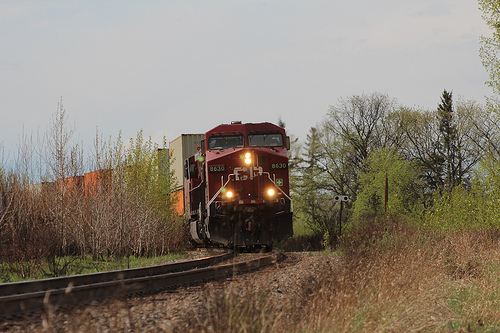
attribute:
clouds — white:
[2, 3, 487, 162]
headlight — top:
[241, 148, 254, 158]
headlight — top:
[240, 157, 254, 167]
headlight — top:
[262, 184, 279, 199]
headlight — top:
[222, 186, 236, 201]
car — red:
[182, 115, 294, 255]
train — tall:
[25, 120, 295, 250]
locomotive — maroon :
[189, 117, 296, 250]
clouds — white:
[46, 21, 196, 81]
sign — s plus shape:
[250, 161, 298, 192]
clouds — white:
[216, 15, 296, 55]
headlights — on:
[209, 155, 299, 212]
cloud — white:
[425, 19, 456, 96]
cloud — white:
[370, 13, 417, 64]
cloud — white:
[290, 20, 337, 101]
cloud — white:
[204, 10, 252, 66]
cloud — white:
[110, 15, 166, 94]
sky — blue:
[1, 6, 483, 177]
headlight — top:
[242, 150, 252, 164]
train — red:
[204, 119, 294, 253]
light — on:
[267, 187, 274, 195]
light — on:
[226, 189, 234, 198]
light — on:
[246, 158, 251, 164]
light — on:
[244, 152, 251, 157]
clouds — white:
[309, 27, 349, 77]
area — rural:
[0, 122, 490, 327]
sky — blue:
[12, 3, 179, 77]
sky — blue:
[4, 3, 494, 113]